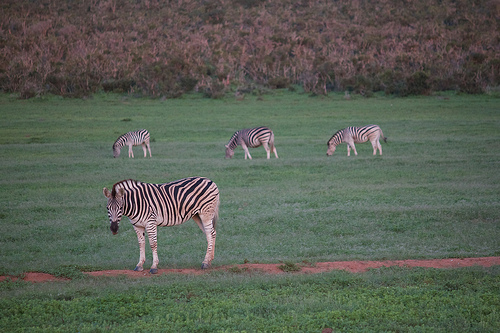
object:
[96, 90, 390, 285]
group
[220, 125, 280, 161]
zebras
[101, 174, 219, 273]
zebra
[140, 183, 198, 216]
stripes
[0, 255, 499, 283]
trail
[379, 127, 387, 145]
tail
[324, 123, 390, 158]
zebra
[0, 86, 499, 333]
field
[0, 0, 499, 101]
bushes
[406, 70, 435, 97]
leaves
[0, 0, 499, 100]
trees